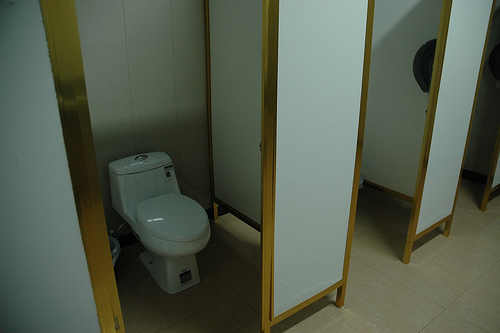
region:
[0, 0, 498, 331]
A public bathroom without doors.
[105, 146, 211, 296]
A toilet with the flush button on top.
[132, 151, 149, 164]
The flush button on top of the toilet.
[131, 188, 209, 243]
A white toilet seat made of plastic.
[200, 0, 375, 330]
The thin wall separating each toilet.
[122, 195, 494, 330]
The ceramic floor below every other item.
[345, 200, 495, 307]
A ceramic tile inside a bathroom.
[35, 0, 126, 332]
A shiny object covering one of the walls.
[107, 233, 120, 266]
The small part of a garbage can near the toilet.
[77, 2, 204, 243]
A wall made of tiles behind the toilet.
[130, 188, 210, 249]
toilet seat is down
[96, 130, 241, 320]
the toilet is white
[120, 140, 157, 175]
silver button on toilet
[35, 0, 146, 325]
outer edge of stall made of wood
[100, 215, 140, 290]
trash can next to toilet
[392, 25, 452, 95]
black object in stall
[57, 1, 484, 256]
stalls have no doors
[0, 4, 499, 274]
the stalls are white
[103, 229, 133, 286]
trash can has bag in it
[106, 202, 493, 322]
the floor is tiled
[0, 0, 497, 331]
the stall is white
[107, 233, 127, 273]
the trash bag is white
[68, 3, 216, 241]
the tile is white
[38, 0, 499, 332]
the stall is trimmed in gold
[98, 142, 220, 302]
the toilet is small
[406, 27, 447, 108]
the toilet paper dispencer is on the wall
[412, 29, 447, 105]
the dispenser is black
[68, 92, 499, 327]
the walls are casting shadows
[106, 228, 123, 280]
the trash can is next to the toilet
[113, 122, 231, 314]
white commode in stall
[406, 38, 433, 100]
toilet paper holder on wall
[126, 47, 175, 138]
tile on back wall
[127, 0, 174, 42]
tile on back wall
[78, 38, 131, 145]
tile on back wall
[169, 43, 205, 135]
tile on back wall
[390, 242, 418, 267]
leg of bathroom stall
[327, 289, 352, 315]
leg of bathroom stall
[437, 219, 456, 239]
leg of bathroom stall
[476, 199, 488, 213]
leg of bathroom stall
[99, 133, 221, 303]
a white toilet in a bathroom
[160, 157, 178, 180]
handle of bathroom on left side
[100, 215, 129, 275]
a trash can can be seen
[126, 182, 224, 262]
lid of bathroom is closed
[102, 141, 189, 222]
tank of toilet is short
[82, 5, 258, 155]
wall of bathroom is white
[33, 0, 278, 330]
brown frame of door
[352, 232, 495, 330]
floor of bathroom is tan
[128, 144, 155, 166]
silver handle on top of tank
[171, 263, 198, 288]
toilet has a label in front